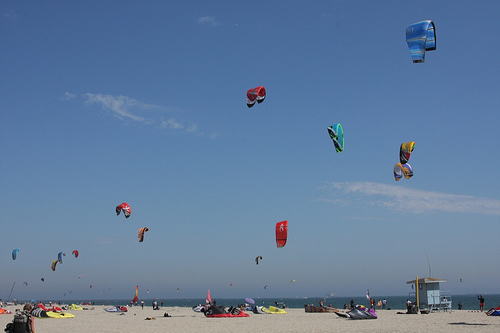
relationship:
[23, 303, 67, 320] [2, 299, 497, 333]
person lying on beach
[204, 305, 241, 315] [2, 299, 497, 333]
person lying on beach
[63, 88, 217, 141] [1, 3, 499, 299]
cloud in sky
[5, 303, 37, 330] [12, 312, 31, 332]
man wearing a backpack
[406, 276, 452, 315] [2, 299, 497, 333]
tower sitting on beach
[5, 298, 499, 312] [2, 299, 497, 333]
ocean beside beach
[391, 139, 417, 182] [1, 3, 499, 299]
kite in sky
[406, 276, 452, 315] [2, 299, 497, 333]
tower on beach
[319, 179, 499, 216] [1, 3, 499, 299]
cloud in sky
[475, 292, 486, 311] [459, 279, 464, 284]
man flying a kite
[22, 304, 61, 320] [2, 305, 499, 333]
lady laying on sand